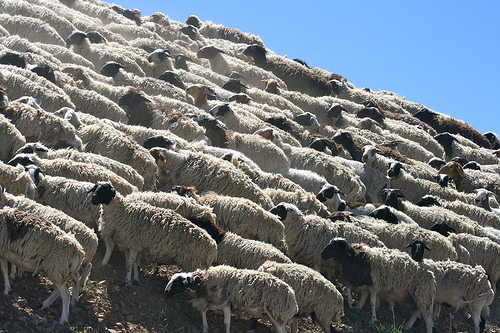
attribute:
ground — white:
[414, 129, 434, 161]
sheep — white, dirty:
[432, 127, 499, 167]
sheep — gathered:
[74, 100, 432, 314]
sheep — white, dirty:
[170, 256, 305, 327]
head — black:
[163, 270, 188, 299]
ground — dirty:
[429, 143, 468, 181]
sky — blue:
[311, 27, 498, 57]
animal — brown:
[336, 135, 412, 172]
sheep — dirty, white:
[87, 176, 215, 288]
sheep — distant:
[188, 14, 267, 46]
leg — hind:
[196, 306, 237, 331]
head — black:
[91, 179, 112, 206]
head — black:
[390, 164, 413, 182]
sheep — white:
[390, 161, 425, 197]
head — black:
[406, 240, 429, 260]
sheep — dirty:
[430, 260, 486, 313]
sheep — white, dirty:
[72, 34, 127, 58]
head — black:
[65, 30, 85, 50]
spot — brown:
[8, 209, 39, 244]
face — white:
[291, 165, 350, 208]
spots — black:
[310, 181, 345, 211]